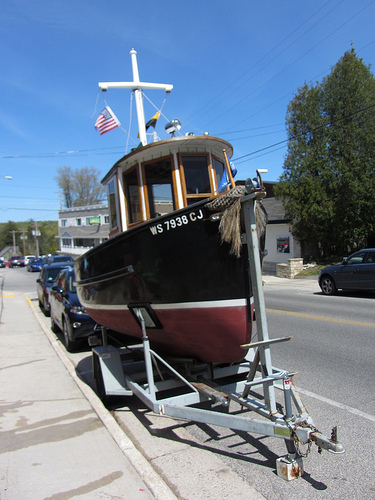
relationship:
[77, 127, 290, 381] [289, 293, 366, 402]
ship in road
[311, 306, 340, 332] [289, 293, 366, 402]
line in road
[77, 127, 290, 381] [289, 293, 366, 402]
ship on road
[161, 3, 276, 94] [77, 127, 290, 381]
sky above ship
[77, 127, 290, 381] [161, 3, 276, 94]
ship below sky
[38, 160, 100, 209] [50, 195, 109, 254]
brown trees behind building